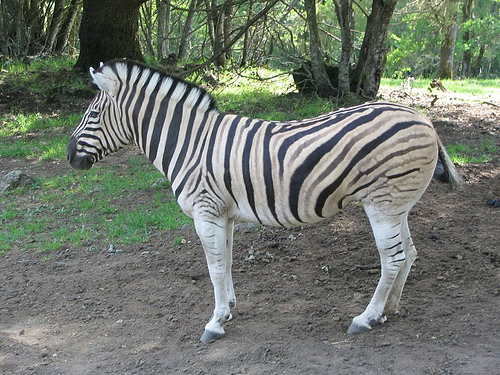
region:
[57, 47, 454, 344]
Zebra is standing in dirt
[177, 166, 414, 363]
Zebra has four legs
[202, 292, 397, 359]
Zebra has hooves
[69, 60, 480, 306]
Zebra has stripes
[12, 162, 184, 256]
Grass is on the ground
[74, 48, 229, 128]
Zebra has a main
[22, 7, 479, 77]
Trees are in the background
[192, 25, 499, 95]
Sun shines through the trees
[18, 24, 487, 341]
The zebra is outdoors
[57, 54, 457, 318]
Zebra is black and white.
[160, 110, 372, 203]
this is the zebras fur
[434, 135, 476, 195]
this is the zebras tail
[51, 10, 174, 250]
the zebra is looking at somthing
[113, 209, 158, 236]
this is grass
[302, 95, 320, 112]
the grass is green in color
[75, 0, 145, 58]
this is the tree trunk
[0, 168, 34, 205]
this is a stone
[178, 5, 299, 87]
this is a tree branches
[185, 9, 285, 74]
the branches are dry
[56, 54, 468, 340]
this is a zebra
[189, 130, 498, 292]
zebra standing in the shade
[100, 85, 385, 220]
the zebra is striped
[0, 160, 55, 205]
rock in the dirt and grass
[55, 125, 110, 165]
zebra has a black nose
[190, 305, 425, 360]
the hoofs of the zebra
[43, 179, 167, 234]
a grass patch in the dirt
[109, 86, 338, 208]
the zebra is black and white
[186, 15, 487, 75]
trees on the right side of the zebra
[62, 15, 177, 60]
large dark tree trunk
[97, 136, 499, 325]
zebra standing in the dirt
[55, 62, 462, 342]
the zebra is white and back in color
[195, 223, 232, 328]
the legs are white in color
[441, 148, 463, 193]
the tail is short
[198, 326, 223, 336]
the hooves are black in color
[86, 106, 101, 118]
the eye is open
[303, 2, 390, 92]
this is a tree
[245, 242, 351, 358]
the soil is black in color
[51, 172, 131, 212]
the grass is green in color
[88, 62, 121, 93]
the ears are wide apart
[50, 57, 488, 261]
zebra is black and white